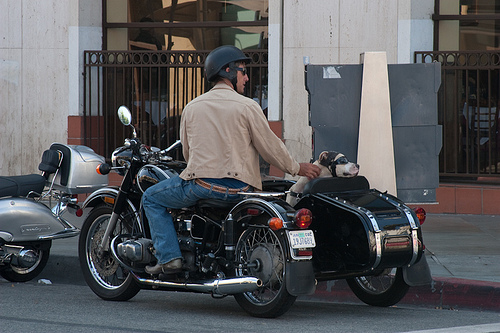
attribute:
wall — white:
[282, 19, 371, 61]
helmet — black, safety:
[194, 42, 260, 87]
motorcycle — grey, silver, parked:
[0, 135, 117, 290]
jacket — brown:
[153, 88, 328, 186]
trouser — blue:
[117, 155, 258, 274]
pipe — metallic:
[121, 258, 269, 312]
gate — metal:
[63, 47, 198, 174]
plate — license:
[275, 224, 319, 253]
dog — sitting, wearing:
[269, 143, 373, 231]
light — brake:
[281, 230, 316, 263]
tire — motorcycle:
[59, 197, 157, 311]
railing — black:
[106, 41, 183, 81]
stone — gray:
[322, 23, 345, 43]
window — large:
[152, 4, 201, 32]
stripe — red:
[56, 105, 93, 140]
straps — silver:
[243, 170, 310, 198]